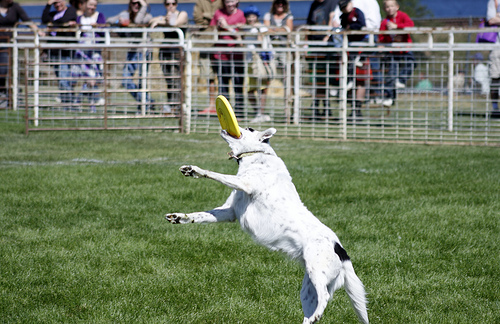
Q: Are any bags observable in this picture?
A: No, there are no bags.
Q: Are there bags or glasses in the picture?
A: No, there are no bags or glasses.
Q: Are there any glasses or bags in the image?
A: No, there are no bags or glasses.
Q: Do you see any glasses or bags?
A: No, there are no bags or glasses.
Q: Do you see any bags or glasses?
A: No, there are no bags or glasses.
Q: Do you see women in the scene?
A: Yes, there are women.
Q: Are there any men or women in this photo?
A: Yes, there are women.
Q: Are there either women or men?
A: Yes, there are women.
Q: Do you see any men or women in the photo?
A: Yes, there are women.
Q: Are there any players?
A: No, there are no players.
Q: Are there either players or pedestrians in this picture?
A: No, there are no players or pedestrians.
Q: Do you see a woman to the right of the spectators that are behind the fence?
A: Yes, there are women to the right of the spectators.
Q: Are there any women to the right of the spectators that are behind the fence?
A: Yes, there are women to the right of the spectators.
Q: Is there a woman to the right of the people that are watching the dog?
A: Yes, there are women to the right of the spectators.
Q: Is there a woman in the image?
A: Yes, there is a woman.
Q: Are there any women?
A: Yes, there is a woman.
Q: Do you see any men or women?
A: Yes, there is a woman.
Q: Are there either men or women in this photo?
A: Yes, there is a woman.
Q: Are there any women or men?
A: Yes, there is a woman.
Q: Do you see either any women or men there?
A: Yes, there is a woman.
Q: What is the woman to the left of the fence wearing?
A: The woman is wearing a shirt.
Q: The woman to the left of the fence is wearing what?
A: The woman is wearing a shirt.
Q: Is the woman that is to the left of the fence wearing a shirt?
A: Yes, the woman is wearing a shirt.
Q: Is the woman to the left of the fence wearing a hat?
A: No, the woman is wearing a shirt.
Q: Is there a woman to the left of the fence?
A: Yes, there is a woman to the left of the fence.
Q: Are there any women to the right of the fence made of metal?
A: No, the woman is to the left of the fence.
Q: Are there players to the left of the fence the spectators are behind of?
A: No, there is a woman to the left of the fence.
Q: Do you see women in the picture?
A: Yes, there is a woman.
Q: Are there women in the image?
A: Yes, there is a woman.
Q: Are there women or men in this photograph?
A: Yes, there is a woman.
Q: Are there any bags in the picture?
A: No, there are no bags.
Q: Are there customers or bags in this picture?
A: No, there are no bags or customers.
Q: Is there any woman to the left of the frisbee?
A: Yes, there is a woman to the left of the frisbee.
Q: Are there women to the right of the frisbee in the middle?
A: No, the woman is to the left of the frisbee.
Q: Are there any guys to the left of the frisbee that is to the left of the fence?
A: No, there is a woman to the left of the frisbee.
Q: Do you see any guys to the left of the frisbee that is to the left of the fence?
A: No, there is a woman to the left of the frisbee.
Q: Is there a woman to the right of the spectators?
A: Yes, there is a woman to the right of the spectators.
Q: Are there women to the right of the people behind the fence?
A: Yes, there is a woman to the right of the spectators.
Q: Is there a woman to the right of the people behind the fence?
A: Yes, there is a woman to the right of the spectators.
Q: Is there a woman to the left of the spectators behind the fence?
A: No, the woman is to the right of the spectators.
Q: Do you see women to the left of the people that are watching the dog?
A: No, the woman is to the right of the spectators.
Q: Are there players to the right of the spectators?
A: No, there is a woman to the right of the spectators.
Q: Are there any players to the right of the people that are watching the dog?
A: No, there is a woman to the right of the spectators.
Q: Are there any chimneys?
A: No, there are no chimneys.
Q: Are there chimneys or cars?
A: No, there are no chimneys or cars.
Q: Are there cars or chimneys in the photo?
A: No, there are no chimneys or cars.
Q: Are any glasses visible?
A: No, there are no glasses.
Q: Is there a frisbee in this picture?
A: Yes, there is a frisbee.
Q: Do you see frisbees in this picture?
A: Yes, there is a frisbee.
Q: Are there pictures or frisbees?
A: Yes, there is a frisbee.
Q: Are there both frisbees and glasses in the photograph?
A: No, there is a frisbee but no glasses.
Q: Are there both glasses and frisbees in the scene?
A: No, there is a frisbee but no glasses.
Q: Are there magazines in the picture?
A: No, there are no magazines.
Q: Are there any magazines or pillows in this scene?
A: No, there are no magazines or pillows.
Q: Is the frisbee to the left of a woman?
A: No, the frisbee is to the right of a woman.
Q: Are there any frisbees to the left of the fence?
A: Yes, there is a frisbee to the left of the fence.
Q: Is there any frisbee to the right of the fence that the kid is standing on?
A: No, the frisbee is to the left of the fence.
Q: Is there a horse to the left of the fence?
A: No, there is a frisbee to the left of the fence.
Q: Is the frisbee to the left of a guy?
A: No, the frisbee is to the left of the fence.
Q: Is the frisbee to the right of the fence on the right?
A: No, the frisbee is to the left of the fence.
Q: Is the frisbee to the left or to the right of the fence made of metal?
A: The frisbee is to the left of the fence.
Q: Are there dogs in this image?
A: Yes, there is a dog.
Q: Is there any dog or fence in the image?
A: Yes, there is a dog.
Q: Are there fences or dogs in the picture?
A: Yes, there is a dog.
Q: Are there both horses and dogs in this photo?
A: No, there is a dog but no horses.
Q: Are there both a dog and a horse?
A: No, there is a dog but no horses.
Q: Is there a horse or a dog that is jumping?
A: Yes, the dog is jumping.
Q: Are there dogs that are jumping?
A: Yes, there is a dog that is jumping.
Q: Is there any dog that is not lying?
A: Yes, there is a dog that is jumping.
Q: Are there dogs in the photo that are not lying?
A: Yes, there is a dog that is jumping.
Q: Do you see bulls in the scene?
A: No, there are no bulls.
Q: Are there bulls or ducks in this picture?
A: No, there are no bulls or ducks.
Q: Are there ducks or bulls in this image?
A: No, there are no bulls or ducks.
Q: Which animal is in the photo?
A: The animal is a dog.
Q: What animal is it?
A: The animal is a dog.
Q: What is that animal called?
A: That is a dog.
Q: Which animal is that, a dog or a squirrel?
A: That is a dog.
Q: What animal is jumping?
A: The animal is a dog.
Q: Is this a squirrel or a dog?
A: This is a dog.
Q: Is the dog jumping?
A: Yes, the dog is jumping.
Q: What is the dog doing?
A: The dog is jumping.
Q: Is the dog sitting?
A: No, the dog is jumping.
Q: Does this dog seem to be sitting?
A: No, the dog is jumping.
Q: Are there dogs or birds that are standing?
A: No, there is a dog but it is jumping.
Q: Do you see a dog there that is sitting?
A: No, there is a dog but it is jumping.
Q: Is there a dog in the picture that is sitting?
A: No, there is a dog but it is jumping.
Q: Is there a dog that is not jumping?
A: No, there is a dog but it is jumping.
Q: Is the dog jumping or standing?
A: The dog is jumping.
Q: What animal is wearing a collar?
A: The dog is wearing a collar.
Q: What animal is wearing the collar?
A: The dog is wearing a collar.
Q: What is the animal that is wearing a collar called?
A: The animal is a dog.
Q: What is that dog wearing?
A: The dog is wearing a collar.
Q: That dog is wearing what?
A: The dog is wearing a collar.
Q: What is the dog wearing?
A: The dog is wearing a collar.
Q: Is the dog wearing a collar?
A: Yes, the dog is wearing a collar.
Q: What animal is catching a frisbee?
A: The dog is catching a frisbee.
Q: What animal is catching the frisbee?
A: The dog is catching a frisbee.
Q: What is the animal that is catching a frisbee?
A: The animal is a dog.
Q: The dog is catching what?
A: The dog is catching a frisbee.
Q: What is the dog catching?
A: The dog is catching a frisbee.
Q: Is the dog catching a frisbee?
A: Yes, the dog is catching a frisbee.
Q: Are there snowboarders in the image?
A: No, there are no snowboarders.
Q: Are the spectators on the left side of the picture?
A: Yes, the spectators are on the left of the image.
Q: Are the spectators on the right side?
A: No, the spectators are on the left of the image.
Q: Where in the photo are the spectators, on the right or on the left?
A: The spectators are on the left of the image.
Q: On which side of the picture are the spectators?
A: The spectators are on the left of the image.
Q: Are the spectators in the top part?
A: Yes, the spectators are in the top of the image.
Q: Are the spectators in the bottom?
A: No, the spectators are in the top of the image.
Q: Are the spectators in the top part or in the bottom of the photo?
A: The spectators are in the top of the image.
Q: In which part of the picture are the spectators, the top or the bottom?
A: The spectators are in the top of the image.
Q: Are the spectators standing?
A: Yes, the spectators are standing.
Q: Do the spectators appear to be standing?
A: Yes, the spectators are standing.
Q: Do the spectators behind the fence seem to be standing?
A: Yes, the spectators are standing.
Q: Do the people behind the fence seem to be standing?
A: Yes, the spectators are standing.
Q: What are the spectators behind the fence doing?
A: The spectators are standing.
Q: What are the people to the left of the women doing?
A: The spectators are standing.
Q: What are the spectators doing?
A: The spectators are standing.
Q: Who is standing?
A: The spectators are standing.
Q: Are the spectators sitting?
A: No, the spectators are standing.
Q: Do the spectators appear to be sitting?
A: No, the spectators are standing.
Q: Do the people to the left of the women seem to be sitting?
A: No, the spectators are standing.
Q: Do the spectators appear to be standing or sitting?
A: The spectators are standing.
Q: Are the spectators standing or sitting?
A: The spectators are standing.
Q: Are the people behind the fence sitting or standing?
A: The spectators are standing.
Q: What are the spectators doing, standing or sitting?
A: The spectators are standing.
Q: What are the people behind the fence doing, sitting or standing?
A: The spectators are standing.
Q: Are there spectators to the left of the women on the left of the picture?
A: Yes, there are spectators to the left of the women.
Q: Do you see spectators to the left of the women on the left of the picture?
A: Yes, there are spectators to the left of the women.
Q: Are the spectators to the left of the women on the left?
A: Yes, the spectators are to the left of the women.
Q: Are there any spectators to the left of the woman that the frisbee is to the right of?
A: Yes, there are spectators to the left of the woman.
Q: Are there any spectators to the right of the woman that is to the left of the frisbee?
A: No, the spectators are to the left of the woman.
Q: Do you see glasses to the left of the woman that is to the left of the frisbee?
A: No, there are spectators to the left of the woman.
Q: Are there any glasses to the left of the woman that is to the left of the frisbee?
A: No, there are spectators to the left of the woman.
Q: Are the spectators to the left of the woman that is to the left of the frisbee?
A: Yes, the spectators are to the left of the woman.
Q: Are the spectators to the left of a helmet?
A: No, the spectators are to the left of the woman.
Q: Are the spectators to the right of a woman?
A: No, the spectators are to the left of a woman.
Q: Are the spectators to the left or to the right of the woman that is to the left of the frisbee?
A: The spectators are to the left of the woman.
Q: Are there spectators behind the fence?
A: Yes, there are spectators behind the fence.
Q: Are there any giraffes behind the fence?
A: No, there are spectators behind the fence.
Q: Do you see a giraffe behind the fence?
A: No, there are spectators behind the fence.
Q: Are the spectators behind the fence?
A: Yes, the spectators are behind the fence.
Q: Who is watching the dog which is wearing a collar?
A: The spectators are watching the dog.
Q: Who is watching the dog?
A: The spectators are watching the dog.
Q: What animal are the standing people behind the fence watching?
A: The spectators are watching the dog.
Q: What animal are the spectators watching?
A: The spectators are watching the dog.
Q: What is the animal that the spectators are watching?
A: The animal is a dog.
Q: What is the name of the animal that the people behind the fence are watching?
A: The animal is a dog.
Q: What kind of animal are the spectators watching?
A: The spectators are watching the dog.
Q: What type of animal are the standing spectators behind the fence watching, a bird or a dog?
A: The spectators are watching a dog.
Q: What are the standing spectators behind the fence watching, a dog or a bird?
A: The spectators are watching a dog.